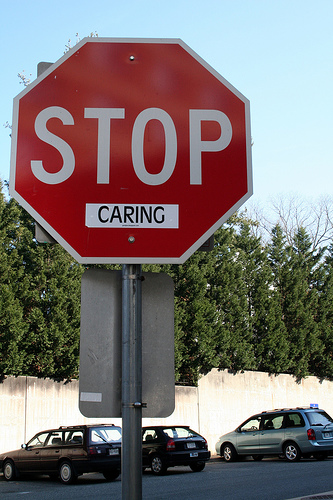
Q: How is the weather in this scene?
A: It is clear.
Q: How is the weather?
A: It is clear.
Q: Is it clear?
A: Yes, it is clear.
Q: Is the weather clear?
A: Yes, it is clear.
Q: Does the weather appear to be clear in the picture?
A: Yes, it is clear.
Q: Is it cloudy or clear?
A: It is clear.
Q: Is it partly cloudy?
A: No, it is clear.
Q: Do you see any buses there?
A: No, there are no buses.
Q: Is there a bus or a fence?
A: No, there are no buses or fences.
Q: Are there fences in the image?
A: No, there are no fences.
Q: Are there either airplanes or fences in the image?
A: No, there are no fences or airplanes.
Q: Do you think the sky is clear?
A: Yes, the sky is clear.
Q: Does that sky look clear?
A: Yes, the sky is clear.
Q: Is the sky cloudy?
A: No, the sky is clear.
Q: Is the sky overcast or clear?
A: The sky is clear.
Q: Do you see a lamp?
A: No, there are no lamps.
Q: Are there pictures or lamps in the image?
A: No, there are no lamps or pictures.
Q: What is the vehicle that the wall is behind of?
A: The vehicle is a van.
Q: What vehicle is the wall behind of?
A: The wall is behind the van.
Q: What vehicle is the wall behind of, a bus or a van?
A: The wall is behind a van.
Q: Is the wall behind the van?
A: Yes, the wall is behind the van.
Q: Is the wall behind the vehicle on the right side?
A: Yes, the wall is behind the van.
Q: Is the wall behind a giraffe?
A: No, the wall is behind the van.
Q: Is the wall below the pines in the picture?
A: Yes, the wall is below the pines.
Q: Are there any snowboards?
A: No, there are no snowboards.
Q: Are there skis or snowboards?
A: No, there are no snowboards or skis.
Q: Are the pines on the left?
A: No, the pines are on the right of the image.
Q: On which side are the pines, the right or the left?
A: The pines are on the right of the image.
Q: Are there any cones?
A: No, there are no cones.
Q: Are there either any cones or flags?
A: No, there are no cones or flags.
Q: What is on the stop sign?
A: The sticker is on the stop sign.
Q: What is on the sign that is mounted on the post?
A: The sticker is on the stop sign.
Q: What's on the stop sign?
A: The sticker is on the stop sign.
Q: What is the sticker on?
A: The sticker is on the stop sign.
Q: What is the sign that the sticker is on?
A: The sign is a stop sign.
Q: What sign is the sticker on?
A: The sticker is on the stop sign.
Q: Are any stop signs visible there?
A: Yes, there is a stop sign.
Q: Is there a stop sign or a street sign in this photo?
A: Yes, there is a stop sign.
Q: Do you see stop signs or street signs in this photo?
A: Yes, there is a stop sign.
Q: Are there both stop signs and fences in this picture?
A: No, there is a stop sign but no fences.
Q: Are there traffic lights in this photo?
A: No, there are no traffic lights.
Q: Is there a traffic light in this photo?
A: No, there are no traffic lights.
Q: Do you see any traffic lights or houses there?
A: No, there are no traffic lights or houses.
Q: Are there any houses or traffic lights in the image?
A: No, there are no traffic lights or houses.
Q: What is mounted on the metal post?
A: The stop sign is mounted on the post.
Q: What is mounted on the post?
A: The stop sign is mounted on the post.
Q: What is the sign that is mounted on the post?
A: The sign is a stop sign.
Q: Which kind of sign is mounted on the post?
A: The sign is a stop sign.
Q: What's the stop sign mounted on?
A: The stop sign is mounted on the post.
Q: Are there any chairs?
A: No, there are no chairs.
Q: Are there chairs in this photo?
A: No, there are no chairs.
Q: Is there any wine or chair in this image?
A: No, there are no chairs or wine.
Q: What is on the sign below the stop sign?
A: The label is on the sign.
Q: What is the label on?
A: The label is on the sign.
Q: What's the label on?
A: The label is on the sign.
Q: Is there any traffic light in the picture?
A: No, there are no traffic lights.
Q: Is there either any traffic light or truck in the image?
A: No, there are no traffic lights or trucks.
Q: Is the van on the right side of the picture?
A: Yes, the van is on the right of the image.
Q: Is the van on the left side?
A: No, the van is on the right of the image.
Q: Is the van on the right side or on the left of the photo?
A: The van is on the right of the image.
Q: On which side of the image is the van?
A: The van is on the right of the image.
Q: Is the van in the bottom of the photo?
A: Yes, the van is in the bottom of the image.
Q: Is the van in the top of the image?
A: No, the van is in the bottom of the image.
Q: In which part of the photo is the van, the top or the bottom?
A: The van is in the bottom of the image.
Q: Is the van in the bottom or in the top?
A: The van is in the bottom of the image.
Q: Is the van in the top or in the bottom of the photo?
A: The van is in the bottom of the image.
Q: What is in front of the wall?
A: The van is in front of the wall.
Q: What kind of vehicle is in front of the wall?
A: The vehicle is a van.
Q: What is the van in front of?
A: The van is in front of the wall.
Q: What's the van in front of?
A: The van is in front of the wall.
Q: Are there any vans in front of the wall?
A: Yes, there is a van in front of the wall.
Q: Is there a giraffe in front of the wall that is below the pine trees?
A: No, there is a van in front of the wall.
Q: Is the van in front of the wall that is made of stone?
A: Yes, the van is in front of the wall.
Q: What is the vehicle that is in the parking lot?
A: The vehicle is a van.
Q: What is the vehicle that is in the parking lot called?
A: The vehicle is a van.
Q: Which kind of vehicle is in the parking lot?
A: The vehicle is a van.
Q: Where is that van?
A: The van is in the parking lot.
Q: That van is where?
A: The van is in the parking lot.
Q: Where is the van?
A: The van is in the parking lot.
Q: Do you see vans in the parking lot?
A: Yes, there is a van in the parking lot.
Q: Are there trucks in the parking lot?
A: No, there is a van in the parking lot.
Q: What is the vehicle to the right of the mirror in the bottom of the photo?
A: The vehicle is a van.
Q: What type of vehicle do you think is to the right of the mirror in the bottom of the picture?
A: The vehicle is a van.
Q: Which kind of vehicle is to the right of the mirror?
A: The vehicle is a van.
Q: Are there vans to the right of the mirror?
A: Yes, there is a van to the right of the mirror.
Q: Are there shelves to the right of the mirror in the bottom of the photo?
A: No, there is a van to the right of the mirror.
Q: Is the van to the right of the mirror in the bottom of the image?
A: Yes, the van is to the right of the mirror.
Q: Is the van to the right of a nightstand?
A: No, the van is to the right of the mirror.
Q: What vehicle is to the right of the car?
A: The vehicle is a van.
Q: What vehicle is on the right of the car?
A: The vehicle is a van.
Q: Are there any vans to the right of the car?
A: Yes, there is a van to the right of the car.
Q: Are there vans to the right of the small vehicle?
A: Yes, there is a van to the right of the car.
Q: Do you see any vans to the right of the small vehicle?
A: Yes, there is a van to the right of the car.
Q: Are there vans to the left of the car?
A: No, the van is to the right of the car.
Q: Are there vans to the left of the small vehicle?
A: No, the van is to the right of the car.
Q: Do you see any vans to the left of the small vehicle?
A: No, the van is to the right of the car.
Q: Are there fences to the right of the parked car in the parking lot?
A: No, there is a van to the right of the car.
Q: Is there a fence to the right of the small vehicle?
A: No, there is a van to the right of the car.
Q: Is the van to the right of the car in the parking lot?
A: Yes, the van is to the right of the car.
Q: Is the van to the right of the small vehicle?
A: Yes, the van is to the right of the car.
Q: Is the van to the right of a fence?
A: No, the van is to the right of the car.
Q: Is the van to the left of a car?
A: No, the van is to the right of a car.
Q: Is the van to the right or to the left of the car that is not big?
A: The van is to the right of the car.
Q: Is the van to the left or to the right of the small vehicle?
A: The van is to the right of the car.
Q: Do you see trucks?
A: No, there are no trucks.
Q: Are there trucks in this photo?
A: No, there are no trucks.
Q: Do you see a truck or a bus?
A: No, there are no trucks or buses.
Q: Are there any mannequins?
A: No, there are no mannequins.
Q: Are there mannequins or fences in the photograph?
A: No, there are no mannequins or fences.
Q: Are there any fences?
A: No, there are no fences.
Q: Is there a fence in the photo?
A: No, there are no fences.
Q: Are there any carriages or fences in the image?
A: No, there are no fences or carriages.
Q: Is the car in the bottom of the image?
A: Yes, the car is in the bottom of the image.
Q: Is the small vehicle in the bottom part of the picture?
A: Yes, the car is in the bottom of the image.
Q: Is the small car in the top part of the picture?
A: No, the car is in the bottom of the image.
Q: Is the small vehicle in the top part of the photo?
A: No, the car is in the bottom of the image.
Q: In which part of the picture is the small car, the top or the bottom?
A: The car is in the bottom of the image.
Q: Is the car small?
A: Yes, the car is small.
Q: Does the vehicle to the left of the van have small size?
A: Yes, the car is small.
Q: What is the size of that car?
A: The car is small.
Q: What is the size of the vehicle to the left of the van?
A: The car is small.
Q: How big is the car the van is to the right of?
A: The car is small.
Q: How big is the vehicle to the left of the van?
A: The car is small.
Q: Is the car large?
A: No, the car is small.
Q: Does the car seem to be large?
A: No, the car is small.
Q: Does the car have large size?
A: No, the car is small.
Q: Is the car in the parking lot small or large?
A: The car is small.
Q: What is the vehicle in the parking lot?
A: The vehicle is a car.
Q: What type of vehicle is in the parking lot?
A: The vehicle is a car.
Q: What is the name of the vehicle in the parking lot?
A: The vehicle is a car.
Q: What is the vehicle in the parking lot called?
A: The vehicle is a car.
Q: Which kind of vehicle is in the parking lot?
A: The vehicle is a car.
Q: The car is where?
A: The car is in the parking lot.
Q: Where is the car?
A: The car is in the parking lot.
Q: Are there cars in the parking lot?
A: Yes, there is a car in the parking lot.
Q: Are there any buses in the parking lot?
A: No, there is a car in the parking lot.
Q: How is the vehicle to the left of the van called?
A: The vehicle is a car.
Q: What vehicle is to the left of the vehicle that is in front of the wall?
A: The vehicle is a car.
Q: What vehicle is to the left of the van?
A: The vehicle is a car.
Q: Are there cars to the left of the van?
A: Yes, there is a car to the left of the van.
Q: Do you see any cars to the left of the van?
A: Yes, there is a car to the left of the van.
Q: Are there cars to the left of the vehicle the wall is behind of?
A: Yes, there is a car to the left of the van.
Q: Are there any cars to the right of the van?
A: No, the car is to the left of the van.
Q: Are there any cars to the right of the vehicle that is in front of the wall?
A: No, the car is to the left of the van.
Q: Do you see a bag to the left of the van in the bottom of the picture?
A: No, there is a car to the left of the van.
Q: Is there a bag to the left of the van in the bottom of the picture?
A: No, there is a car to the left of the van.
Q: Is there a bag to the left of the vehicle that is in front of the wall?
A: No, there is a car to the left of the van.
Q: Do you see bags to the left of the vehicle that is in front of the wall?
A: No, there is a car to the left of the van.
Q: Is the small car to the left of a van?
A: Yes, the car is to the left of a van.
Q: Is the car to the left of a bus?
A: No, the car is to the left of a van.